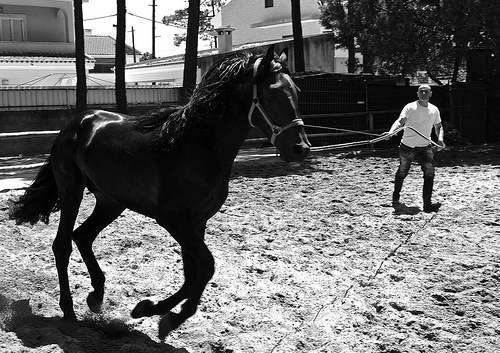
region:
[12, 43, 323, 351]
The horse is black.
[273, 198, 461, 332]
Shadow of the rope.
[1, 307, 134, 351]
Shadow of the horse.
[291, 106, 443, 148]
The man is holding the rope.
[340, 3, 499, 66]
Tree in the background.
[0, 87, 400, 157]
Fence in the background.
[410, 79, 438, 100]
The man is bald.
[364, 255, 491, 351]
The ground is bare.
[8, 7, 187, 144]
Buildings in the background.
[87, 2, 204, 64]
The sky is white.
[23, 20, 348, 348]
a black horse running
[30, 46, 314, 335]
a black horse with harness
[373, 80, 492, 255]
a man holding a rope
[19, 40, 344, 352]
a horse running in the field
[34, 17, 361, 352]
a horse running in a field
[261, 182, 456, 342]
a dirt field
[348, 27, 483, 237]
a man wearing jeans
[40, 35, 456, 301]
a man and a horse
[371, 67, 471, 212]
a man wearing a white shirt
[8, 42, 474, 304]
a horse with a rope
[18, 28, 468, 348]
a man with a horse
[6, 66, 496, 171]
a fence behind the man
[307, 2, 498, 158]
a tree behind the fence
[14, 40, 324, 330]
the horse is running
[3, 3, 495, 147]
houses behind the fence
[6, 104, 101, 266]
the horse has a tail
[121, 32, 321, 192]
the horse's mane is long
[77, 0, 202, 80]
power lines in between the houses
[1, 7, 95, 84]
the house has a window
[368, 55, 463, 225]
the man is standing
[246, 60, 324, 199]
Horse has straps on face.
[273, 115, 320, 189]
Horse has black nose.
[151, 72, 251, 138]
Horse has black mane.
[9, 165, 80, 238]
Horse has black tail.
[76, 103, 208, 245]
Horse has black back.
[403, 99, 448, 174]
Man is wearing white shirt.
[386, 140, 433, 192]
Man is wearing dark pants.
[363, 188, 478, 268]
Man is standing in dirt area.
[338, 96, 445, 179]
Man is holding large rope leading horse.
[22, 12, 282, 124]
Tall trees behind horse.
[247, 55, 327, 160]
The harness on the horse's head and face.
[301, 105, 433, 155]
The ropes the man is using to lead the horse.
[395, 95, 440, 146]
The white shirt the man is wearing.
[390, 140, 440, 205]
The black pants the man is wearing.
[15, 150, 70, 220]
The tail of the horse.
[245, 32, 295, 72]
The ears of the horse.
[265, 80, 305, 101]
The eyes of the horse.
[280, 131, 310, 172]
The nose and mouth of the horse.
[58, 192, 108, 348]
The back legs of the horse.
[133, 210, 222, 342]
The front legs of the horse.